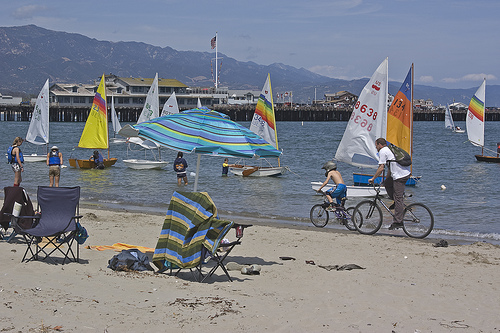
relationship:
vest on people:
[0, 124, 119, 202] [5, 130, 118, 198]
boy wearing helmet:
[290, 146, 377, 221] [309, 154, 348, 177]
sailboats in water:
[16, 57, 497, 239] [137, 117, 498, 229]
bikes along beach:
[271, 158, 448, 246] [139, 77, 469, 309]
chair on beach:
[15, 175, 93, 267] [65, 57, 466, 313]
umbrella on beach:
[120, 79, 293, 223] [68, 74, 404, 330]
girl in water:
[154, 144, 206, 189] [436, 135, 470, 173]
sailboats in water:
[16, 57, 497, 239] [426, 143, 466, 175]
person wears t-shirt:
[368, 137, 422, 226] [366, 136, 416, 190]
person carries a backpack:
[368, 137, 422, 226] [379, 136, 426, 172]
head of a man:
[367, 131, 394, 161] [363, 141, 432, 217]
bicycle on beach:
[349, 190, 442, 244] [168, 77, 431, 284]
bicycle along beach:
[349, 190, 442, 244] [108, 92, 408, 288]